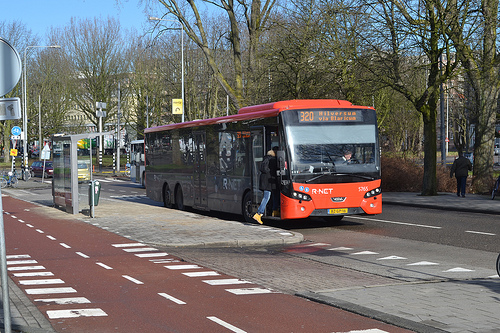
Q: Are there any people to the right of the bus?
A: Yes, there is a person to the right of the bus.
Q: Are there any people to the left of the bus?
A: No, the person is to the right of the bus.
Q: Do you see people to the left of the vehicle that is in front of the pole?
A: No, the person is to the right of the bus.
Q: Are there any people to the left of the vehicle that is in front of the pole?
A: No, the person is to the right of the bus.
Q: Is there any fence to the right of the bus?
A: No, there is a person to the right of the bus.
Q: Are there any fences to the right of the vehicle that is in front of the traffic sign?
A: No, there is a person to the right of the bus.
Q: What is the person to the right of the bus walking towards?
A: The person is walking towards the trees.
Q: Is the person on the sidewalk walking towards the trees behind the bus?
A: Yes, the person is walking towards the trees.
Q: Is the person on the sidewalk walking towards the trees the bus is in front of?
A: Yes, the person is walking towards the trees.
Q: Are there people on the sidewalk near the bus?
A: Yes, there is a person on the sidewalk.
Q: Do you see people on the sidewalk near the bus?
A: Yes, there is a person on the sidewalk.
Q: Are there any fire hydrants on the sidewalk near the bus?
A: No, there is a person on the sidewalk.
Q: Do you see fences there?
A: No, there are no fences.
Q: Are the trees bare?
A: Yes, the trees are bare.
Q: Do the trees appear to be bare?
A: Yes, the trees are bare.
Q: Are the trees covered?
A: No, the trees are bare.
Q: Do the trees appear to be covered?
A: No, the trees are bare.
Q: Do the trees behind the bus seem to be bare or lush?
A: The trees are bare.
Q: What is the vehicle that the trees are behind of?
A: The vehicle is a bus.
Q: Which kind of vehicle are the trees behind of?
A: The trees are behind the bus.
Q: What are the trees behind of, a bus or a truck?
A: The trees are behind a bus.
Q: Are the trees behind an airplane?
A: No, the trees are behind the bus.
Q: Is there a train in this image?
A: No, there are no trains.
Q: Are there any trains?
A: No, there are no trains.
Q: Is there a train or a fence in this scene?
A: No, there are no trains or fences.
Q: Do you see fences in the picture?
A: No, there are no fences.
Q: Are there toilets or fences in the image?
A: No, there are no fences or toilets.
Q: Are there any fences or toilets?
A: No, there are no fences or toilets.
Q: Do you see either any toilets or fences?
A: No, there are no fences or toilets.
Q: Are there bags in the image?
A: No, there are no bags.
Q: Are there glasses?
A: No, there are no glasses.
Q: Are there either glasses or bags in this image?
A: No, there are no glasses or bags.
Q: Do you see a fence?
A: No, there are no fences.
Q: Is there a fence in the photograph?
A: No, there are no fences.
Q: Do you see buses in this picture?
A: Yes, there is a bus.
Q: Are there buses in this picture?
A: Yes, there is a bus.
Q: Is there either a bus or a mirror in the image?
A: Yes, there is a bus.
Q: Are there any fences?
A: No, there are no fences.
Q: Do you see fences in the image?
A: No, there are no fences.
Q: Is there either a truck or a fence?
A: No, there are no fences or trucks.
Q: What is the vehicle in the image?
A: The vehicle is a bus.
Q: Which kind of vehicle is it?
A: The vehicle is a bus.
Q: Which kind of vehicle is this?
A: This is a bus.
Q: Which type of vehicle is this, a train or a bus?
A: This is a bus.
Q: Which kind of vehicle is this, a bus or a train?
A: This is a bus.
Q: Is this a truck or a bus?
A: This is a bus.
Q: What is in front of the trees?
A: The bus is in front of the trees.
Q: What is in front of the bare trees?
A: The bus is in front of the trees.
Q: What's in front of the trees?
A: The bus is in front of the trees.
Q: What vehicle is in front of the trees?
A: The vehicle is a bus.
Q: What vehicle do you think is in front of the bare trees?
A: The vehicle is a bus.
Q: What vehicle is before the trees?
A: The vehicle is a bus.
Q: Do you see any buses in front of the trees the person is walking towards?
A: Yes, there is a bus in front of the trees.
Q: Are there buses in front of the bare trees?
A: Yes, there is a bus in front of the trees.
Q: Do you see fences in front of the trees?
A: No, there is a bus in front of the trees.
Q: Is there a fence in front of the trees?
A: No, there is a bus in front of the trees.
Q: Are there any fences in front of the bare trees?
A: No, there is a bus in front of the trees.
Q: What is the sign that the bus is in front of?
A: The sign is a traffic sign.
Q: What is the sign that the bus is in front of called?
A: The sign is a traffic sign.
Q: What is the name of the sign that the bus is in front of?
A: The sign is a traffic sign.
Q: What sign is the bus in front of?
A: The bus is in front of the traffic sign.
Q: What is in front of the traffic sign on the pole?
A: The bus is in front of the traffic sign.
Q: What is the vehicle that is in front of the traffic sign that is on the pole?
A: The vehicle is a bus.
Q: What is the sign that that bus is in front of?
A: The sign is a traffic sign.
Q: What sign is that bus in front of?
A: The bus is in front of the traffic sign.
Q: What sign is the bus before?
A: The bus is in front of the traffic sign.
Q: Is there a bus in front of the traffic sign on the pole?
A: Yes, there is a bus in front of the traffic sign.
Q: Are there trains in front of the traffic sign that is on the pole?
A: No, there is a bus in front of the traffic sign.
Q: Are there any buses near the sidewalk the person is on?
A: Yes, there is a bus near the sidewalk.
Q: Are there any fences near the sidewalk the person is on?
A: No, there is a bus near the sidewalk.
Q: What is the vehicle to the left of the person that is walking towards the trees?
A: The vehicle is a bus.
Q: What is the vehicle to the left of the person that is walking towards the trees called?
A: The vehicle is a bus.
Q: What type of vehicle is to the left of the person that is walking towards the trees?
A: The vehicle is a bus.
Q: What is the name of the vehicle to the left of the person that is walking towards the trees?
A: The vehicle is a bus.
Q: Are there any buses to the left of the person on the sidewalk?
A: Yes, there is a bus to the left of the person.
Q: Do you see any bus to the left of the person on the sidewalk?
A: Yes, there is a bus to the left of the person.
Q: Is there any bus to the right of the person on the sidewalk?
A: No, the bus is to the left of the person.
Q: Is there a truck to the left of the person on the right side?
A: No, there is a bus to the left of the person.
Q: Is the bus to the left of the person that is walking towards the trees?
A: Yes, the bus is to the left of the person.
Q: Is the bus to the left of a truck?
A: No, the bus is to the left of the person.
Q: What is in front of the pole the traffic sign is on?
A: The bus is in front of the pole.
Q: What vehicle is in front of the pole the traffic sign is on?
A: The vehicle is a bus.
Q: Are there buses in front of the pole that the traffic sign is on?
A: Yes, there is a bus in front of the pole.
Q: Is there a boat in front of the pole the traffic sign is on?
A: No, there is a bus in front of the pole.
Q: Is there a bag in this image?
A: No, there are no bags.